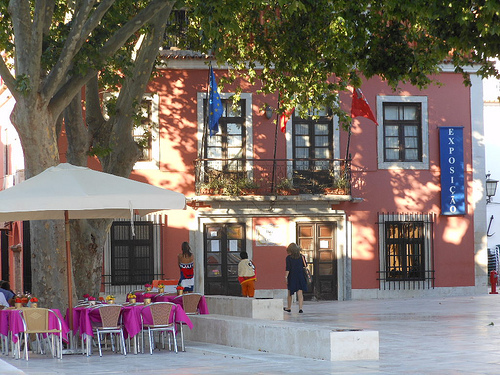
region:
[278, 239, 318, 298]
lady wearing blue dress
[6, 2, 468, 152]
it is a big tree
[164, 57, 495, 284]
it is big building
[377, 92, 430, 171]
it is glass window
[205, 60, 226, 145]
it is blue color flag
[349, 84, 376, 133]
it is red color flag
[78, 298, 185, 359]
it is chair in ground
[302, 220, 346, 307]
it is a front door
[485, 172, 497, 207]
it is lamp in the building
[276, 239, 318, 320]
woman black dress walking toward building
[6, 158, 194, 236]
tan umbrella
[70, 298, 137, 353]
table with bright pink table cloth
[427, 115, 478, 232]
blue sign with white letters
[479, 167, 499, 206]
wall lantern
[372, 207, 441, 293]
metal cage covering window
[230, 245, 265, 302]
woman in red pants and tan shirt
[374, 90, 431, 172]
brown wood framed window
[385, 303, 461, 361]
gray cement walkway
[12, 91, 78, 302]
brown tree trunk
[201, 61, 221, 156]
blue flag on the pole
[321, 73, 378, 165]
red flag on a pole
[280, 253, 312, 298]
woman wearing a blue dress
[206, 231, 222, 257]
paper on the door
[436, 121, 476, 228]
blue sign on the building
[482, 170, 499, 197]
lamp on the building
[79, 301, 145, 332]
purple table cloth on the table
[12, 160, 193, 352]
umbrella on the ground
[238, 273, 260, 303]
woman wearing orange pants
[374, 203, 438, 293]
metal gate on a window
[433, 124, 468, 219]
a banner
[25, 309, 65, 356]
a chair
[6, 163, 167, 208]
a big umbrella that is white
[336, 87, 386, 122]
a red flag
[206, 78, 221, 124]
a blue flag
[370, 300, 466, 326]
a shadow on the ground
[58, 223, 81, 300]
a brown pole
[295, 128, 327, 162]
a window on the building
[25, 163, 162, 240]
a large white umbrella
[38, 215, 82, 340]
a long brown umbrella pole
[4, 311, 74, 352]
a table covered by a purple cloth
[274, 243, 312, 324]
a woman wearing a black dress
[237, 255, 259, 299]
a woman wearing orange pants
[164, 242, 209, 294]
a woman wearing a maxi dress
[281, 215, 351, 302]
a large brown front door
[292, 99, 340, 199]
a large window with sections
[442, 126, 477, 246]
a large blue and white sign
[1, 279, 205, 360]
The outdoor sitting arrangement.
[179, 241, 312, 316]
The three women outside the building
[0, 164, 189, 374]
A white outdoor umbrella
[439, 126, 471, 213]
The blue signboard with white writings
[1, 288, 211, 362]
The pink chair arrangement outdoors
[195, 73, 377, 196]
The three flags mounted on the building.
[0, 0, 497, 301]
The brown painted building.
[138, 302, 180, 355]
a brown patio chair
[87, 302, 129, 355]
a brown patio chair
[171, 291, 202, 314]
a brown patio chaira brown patio chair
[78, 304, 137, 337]
a bright pink tablecloth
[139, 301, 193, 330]
a bright pink tablecloth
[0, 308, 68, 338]
a bright pink tablecloth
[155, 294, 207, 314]
a bright pink tablecloth